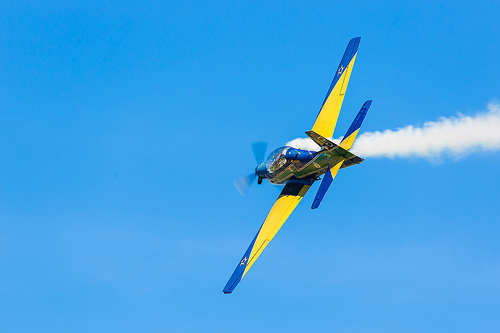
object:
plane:
[222, 36, 374, 294]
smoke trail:
[281, 98, 499, 166]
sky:
[0, 0, 500, 332]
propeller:
[233, 140, 284, 193]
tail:
[303, 130, 364, 165]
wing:
[223, 180, 315, 293]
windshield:
[263, 145, 287, 173]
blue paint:
[311, 36, 361, 129]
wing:
[303, 37, 362, 142]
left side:
[218, 157, 342, 294]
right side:
[298, 35, 373, 151]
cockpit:
[264, 144, 307, 174]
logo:
[306, 132, 332, 153]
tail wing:
[337, 100, 373, 152]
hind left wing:
[307, 157, 348, 210]